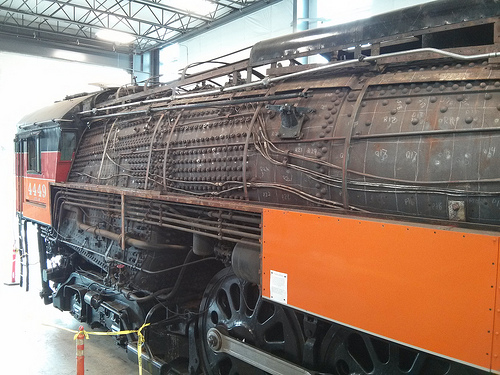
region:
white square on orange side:
[264, 267, 306, 317]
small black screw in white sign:
[265, 268, 275, 276]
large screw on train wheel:
[198, 327, 259, 362]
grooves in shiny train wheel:
[208, 282, 249, 319]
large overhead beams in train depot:
[108, 4, 220, 44]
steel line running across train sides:
[220, 125, 471, 221]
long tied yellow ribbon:
[52, 314, 170, 334]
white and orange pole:
[62, 325, 99, 374]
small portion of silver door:
[12, 40, 140, 69]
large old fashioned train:
[17, 26, 498, 364]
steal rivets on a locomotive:
[181, 148, 243, 175]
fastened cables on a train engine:
[258, 135, 345, 192]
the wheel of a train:
[195, 268, 284, 373]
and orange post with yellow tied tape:
[63, 320, 102, 363]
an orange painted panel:
[300, 217, 414, 320]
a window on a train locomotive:
[24, 136, 45, 171]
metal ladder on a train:
[15, 217, 39, 282]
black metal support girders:
[60, 4, 147, 38]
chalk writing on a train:
[358, 137, 431, 168]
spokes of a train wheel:
[226, 290, 261, 317]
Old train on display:
[65, 96, 485, 243]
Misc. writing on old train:
[360, 85, 495, 205]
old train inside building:
[20, 65, 420, 310]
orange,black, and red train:
[15, 107, 68, 222]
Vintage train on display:
[55, 105, 380, 370]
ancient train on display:
[45, 97, 487, 369]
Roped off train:
[15, 260, 150, 370]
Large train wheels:
[215, 267, 310, 367]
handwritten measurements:
[272, 97, 492, 227]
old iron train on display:
[70, 100, 416, 372]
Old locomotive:
[8, 5, 498, 372]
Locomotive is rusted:
[55, 92, 477, 222]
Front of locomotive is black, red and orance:
[1, 81, 87, 265]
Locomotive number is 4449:
[16, 174, 67, 234]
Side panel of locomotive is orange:
[256, 204, 498, 370]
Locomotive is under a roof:
[0, 4, 311, 68]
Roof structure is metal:
[0, 0, 273, 51]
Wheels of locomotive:
[193, 262, 318, 369]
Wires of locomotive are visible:
[98, 93, 489, 219]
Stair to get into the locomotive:
[14, 210, 34, 295]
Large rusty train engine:
[9, 0, 491, 373]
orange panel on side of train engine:
[258, 205, 499, 373]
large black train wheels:
[195, 267, 498, 373]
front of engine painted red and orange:
[11, 90, 96, 228]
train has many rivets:
[68, 95, 265, 202]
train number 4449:
[21, 178, 47, 200]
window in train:
[24, 132, 42, 180]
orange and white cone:
[70, 322, 92, 373]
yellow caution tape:
[45, 312, 151, 372]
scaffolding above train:
[1, 0, 268, 54]